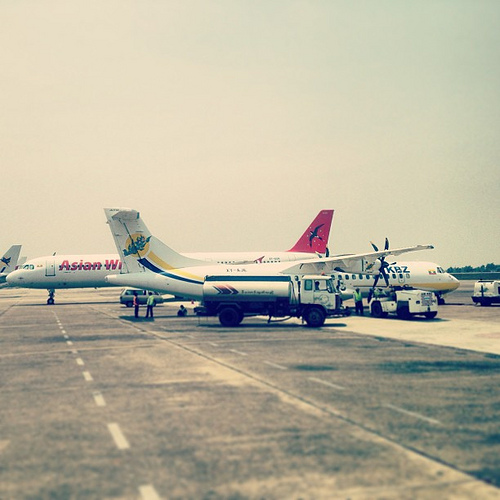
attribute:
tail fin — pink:
[288, 207, 333, 256]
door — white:
[46, 261, 55, 276]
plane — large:
[7, 209, 331, 306]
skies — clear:
[1, 0, 498, 268]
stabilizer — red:
[288, 207, 334, 256]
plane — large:
[97, 203, 465, 345]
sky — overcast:
[2, 1, 496, 271]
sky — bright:
[251, 47, 406, 167]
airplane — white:
[4, 208, 333, 303]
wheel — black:
[42, 287, 62, 312]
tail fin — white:
[103, 207, 218, 269]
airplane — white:
[74, 170, 462, 385]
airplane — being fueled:
[101, 194, 458, 313]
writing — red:
[58, 259, 118, 270]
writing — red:
[385, 265, 410, 275]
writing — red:
[42, 245, 126, 270]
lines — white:
[49, 306, 163, 498]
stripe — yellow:
[127, 230, 229, 283]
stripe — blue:
[135, 257, 212, 291]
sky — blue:
[5, 8, 484, 161]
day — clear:
[0, 1, 484, 494]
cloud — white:
[0, 3, 484, 269]